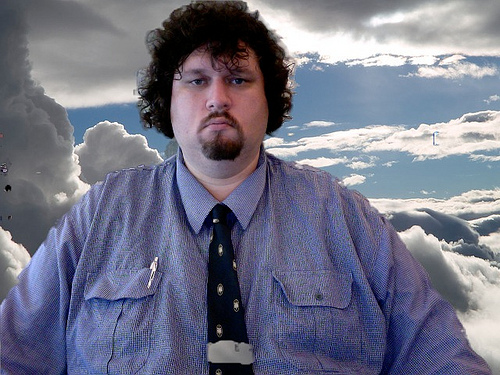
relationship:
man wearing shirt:
[5, 8, 481, 368] [10, 144, 484, 366]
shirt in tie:
[10, 144, 484, 366] [200, 206, 255, 366]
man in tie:
[5, 8, 481, 368] [200, 206, 255, 366]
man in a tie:
[5, 8, 481, 368] [192, 220, 257, 362]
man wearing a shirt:
[5, 8, 481, 368] [4, 168, 484, 368]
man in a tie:
[5, 8, 481, 368] [203, 210, 239, 362]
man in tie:
[0, 1, 491, 375] [202, 205, 248, 370]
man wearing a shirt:
[0, 1, 491, 375] [4, 168, 484, 368]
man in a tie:
[0, 1, 491, 375] [206, 214, 248, 357]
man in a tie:
[0, 1, 491, 375] [198, 208, 250, 367]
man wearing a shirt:
[0, 1, 491, 375] [9, 165, 451, 359]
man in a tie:
[0, 1, 491, 375] [207, 201, 250, 364]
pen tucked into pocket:
[139, 243, 166, 291] [69, 265, 168, 364]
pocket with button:
[272, 267, 359, 365] [310, 285, 330, 299]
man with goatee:
[0, 1, 491, 375] [189, 112, 253, 158]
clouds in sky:
[328, 103, 449, 156] [317, 29, 482, 149]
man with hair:
[0, 1, 491, 375] [139, 10, 302, 121]